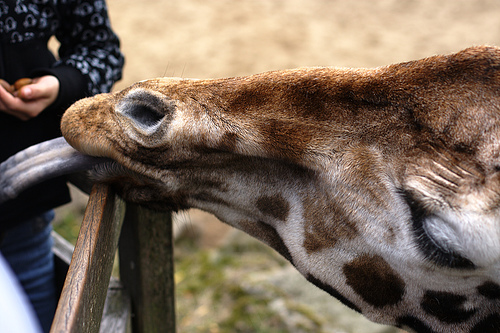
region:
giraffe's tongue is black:
[0, 111, 82, 206]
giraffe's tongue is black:
[0, 128, 67, 198]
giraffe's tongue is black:
[6, 132, 82, 204]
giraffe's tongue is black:
[5, 127, 107, 214]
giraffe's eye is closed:
[389, 162, 494, 308]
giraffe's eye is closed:
[385, 184, 474, 292]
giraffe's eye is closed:
[378, 185, 498, 298]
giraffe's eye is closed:
[366, 174, 493, 306]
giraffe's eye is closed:
[380, 187, 496, 307]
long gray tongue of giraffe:
[6, 134, 90, 195]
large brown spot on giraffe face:
[344, 246, 413, 311]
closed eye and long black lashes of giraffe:
[410, 205, 487, 277]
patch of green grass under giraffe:
[66, 197, 400, 322]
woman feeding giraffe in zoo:
[5, 0, 125, 322]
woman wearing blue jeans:
[4, 213, 61, 321]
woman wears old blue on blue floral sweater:
[6, 0, 128, 216]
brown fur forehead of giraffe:
[172, 48, 497, 131]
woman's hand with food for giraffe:
[1, 68, 68, 115]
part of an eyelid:
[405, 238, 435, 260]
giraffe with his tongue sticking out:
[0, 42, 499, 329]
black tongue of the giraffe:
[0, 131, 104, 198]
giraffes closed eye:
[392, 182, 477, 278]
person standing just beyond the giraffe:
[1, 2, 134, 331]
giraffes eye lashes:
[401, 197, 476, 281]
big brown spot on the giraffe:
[301, 188, 360, 253]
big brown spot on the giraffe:
[342, 248, 409, 313]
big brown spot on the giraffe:
[419, 284, 479, 325]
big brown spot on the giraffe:
[254, 189, 291, 224]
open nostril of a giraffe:
[122, 89, 168, 135]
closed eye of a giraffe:
[406, 196, 473, 270]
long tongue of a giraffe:
[2, 125, 78, 201]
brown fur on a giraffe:
[246, 70, 498, 156]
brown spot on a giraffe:
[340, 243, 410, 311]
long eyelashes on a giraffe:
[397, 209, 452, 276]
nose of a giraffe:
[104, 72, 176, 146]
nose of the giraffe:
[68, 55, 205, 195]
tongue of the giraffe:
[1, 119, 87, 206]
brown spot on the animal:
[329, 235, 417, 318]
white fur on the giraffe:
[351, 190, 427, 266]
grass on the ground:
[197, 263, 283, 332]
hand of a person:
[1, 59, 83, 122]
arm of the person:
[55, 11, 147, 87]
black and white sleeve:
[45, 9, 130, 99]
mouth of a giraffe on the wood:
[60, 48, 482, 303]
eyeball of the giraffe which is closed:
[382, 173, 489, 278]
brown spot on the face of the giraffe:
[331, 240, 416, 305]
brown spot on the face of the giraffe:
[252, 186, 311, 215]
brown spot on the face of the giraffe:
[166, 165, 243, 210]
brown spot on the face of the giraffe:
[222, 68, 279, 128]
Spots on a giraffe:
[296, 195, 406, 307]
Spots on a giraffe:
[252, 181, 412, 307]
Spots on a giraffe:
[242, 178, 370, 265]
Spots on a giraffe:
[244, 179, 361, 282]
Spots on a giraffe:
[288, 183, 410, 312]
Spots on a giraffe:
[235, 176, 362, 269]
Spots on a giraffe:
[248, 183, 361, 268]